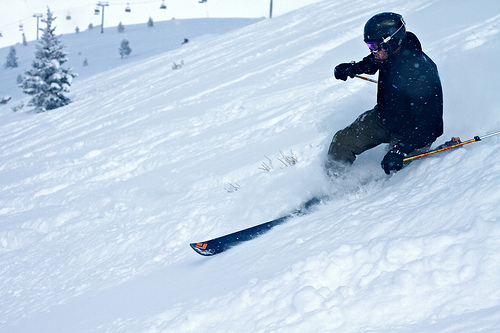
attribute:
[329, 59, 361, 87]
glove — black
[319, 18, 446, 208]
man — dressed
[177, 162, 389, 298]
ski — black, long